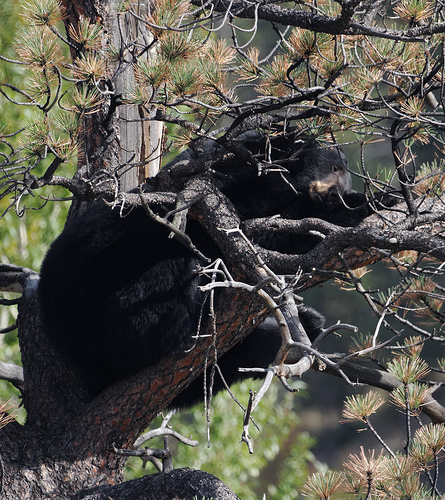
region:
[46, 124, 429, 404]
the bear is black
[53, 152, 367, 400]
the bear is resting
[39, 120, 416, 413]
black bear sleeping in tree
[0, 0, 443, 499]
old fir tree is holding bear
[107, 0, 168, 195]
tree has gap in bark behind bear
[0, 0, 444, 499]
branches of tree are curvy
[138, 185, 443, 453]
one branch of tree is emphy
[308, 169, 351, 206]
bear has brown muzzle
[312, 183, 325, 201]
bear has a mouth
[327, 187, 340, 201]
bear has black nose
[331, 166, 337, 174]
bear has one black eye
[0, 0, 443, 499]
pines are green and brown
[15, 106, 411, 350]
Black bear laying in a tree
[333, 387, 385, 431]
Pine needles on end of tree branch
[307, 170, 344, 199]
Brown nose on black bear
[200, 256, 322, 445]
Bare bark tree branches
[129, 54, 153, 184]
Crack on side of tree trunk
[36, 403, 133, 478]
Bark on side of tree trunk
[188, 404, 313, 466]
Green leaves on tree behind black bear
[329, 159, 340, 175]
Right eye on black bear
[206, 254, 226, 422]
Hanging broken tree branch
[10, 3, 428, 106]
Needle covered tree branches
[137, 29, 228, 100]
Green pine needles in four clumps.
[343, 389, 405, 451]
Pine needles on end of stick.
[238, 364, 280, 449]
Dead branch shaped like a seven.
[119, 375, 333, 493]
Blurry green background behind branches.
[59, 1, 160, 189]
No bark on branch behind pine needles.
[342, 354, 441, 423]
Three clumps of pine needles.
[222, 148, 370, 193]
Animal face is in the tree.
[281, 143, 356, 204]
The animal face is black and tan.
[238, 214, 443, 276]
The crooked branch has a fork.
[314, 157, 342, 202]
One eye is above the nose.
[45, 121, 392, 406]
black bear laying on tree branch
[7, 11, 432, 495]
branches of the pine tree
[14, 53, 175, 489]
trunk of pine tree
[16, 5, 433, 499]
pine straw on branches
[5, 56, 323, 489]
tree behind pine tree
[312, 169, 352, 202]
light brown snout of black bear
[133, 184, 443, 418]
limb black bear is laying on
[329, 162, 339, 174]
eye of black bear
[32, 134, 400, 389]
fur of the black bear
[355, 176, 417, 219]
front paw of black bear